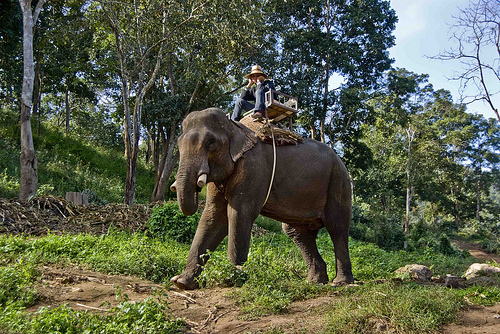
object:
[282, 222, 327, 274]
leg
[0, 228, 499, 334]
dirt path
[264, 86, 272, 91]
elbows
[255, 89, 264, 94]
knees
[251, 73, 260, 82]
face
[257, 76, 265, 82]
hands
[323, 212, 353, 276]
leg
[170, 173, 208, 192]
tusk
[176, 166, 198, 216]
nose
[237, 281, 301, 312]
grass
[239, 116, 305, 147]
blanket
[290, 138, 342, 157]
back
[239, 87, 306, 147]
seat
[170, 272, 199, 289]
foot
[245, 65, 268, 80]
hat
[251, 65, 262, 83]
head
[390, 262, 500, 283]
log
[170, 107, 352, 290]
elephant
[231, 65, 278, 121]
man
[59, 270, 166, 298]
dirt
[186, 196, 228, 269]
leg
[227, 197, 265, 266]
leg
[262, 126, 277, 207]
rope